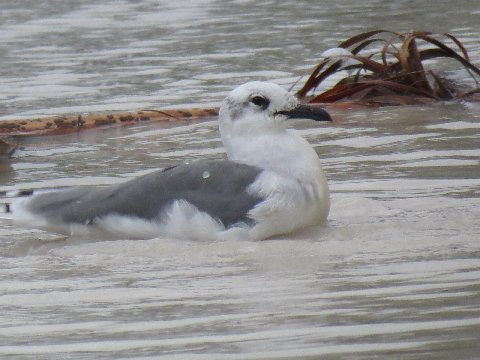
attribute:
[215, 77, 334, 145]
head — bird's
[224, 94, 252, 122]
markings — grey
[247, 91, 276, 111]
eye — black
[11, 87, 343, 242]
duck — white, gray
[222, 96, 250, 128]
marking — gray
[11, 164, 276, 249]
feathers — gray, tail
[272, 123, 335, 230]
chest. — white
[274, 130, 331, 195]
chest — white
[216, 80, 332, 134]
head — white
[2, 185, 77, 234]
feathers — gray, white, tail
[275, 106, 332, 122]
beak — black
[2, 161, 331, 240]
body — white